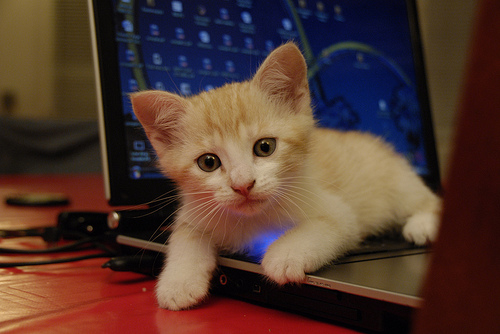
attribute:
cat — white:
[124, 33, 451, 312]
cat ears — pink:
[256, 40, 308, 112]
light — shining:
[245, 230, 285, 260]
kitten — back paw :
[92, 75, 453, 319]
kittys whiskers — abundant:
[174, 187, 320, 223]